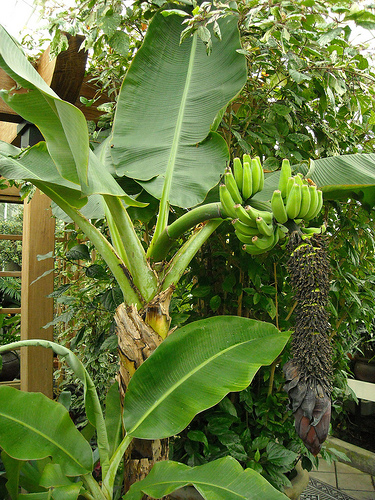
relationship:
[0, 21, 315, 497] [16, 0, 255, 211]
banana tree with leaves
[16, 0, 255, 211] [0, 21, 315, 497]
leaves from banana tree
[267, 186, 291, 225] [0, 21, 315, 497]
banana in banana tree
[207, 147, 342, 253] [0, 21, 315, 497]
bananas on banana tree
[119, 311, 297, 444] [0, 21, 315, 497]
banana leaf on banana tree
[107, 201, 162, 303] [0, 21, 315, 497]
stalk on banana tree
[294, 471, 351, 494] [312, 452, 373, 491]
rug on tile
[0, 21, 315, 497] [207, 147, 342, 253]
banana tree with bananas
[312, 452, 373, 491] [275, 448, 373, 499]
tile on ground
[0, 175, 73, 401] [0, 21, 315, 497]
structure behind banana tree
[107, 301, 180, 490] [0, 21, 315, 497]
trunk of banana tree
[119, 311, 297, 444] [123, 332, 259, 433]
banana leaf with stripe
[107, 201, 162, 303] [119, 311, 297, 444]
stalk from banana leaf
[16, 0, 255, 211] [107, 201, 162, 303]
leaves around stalk